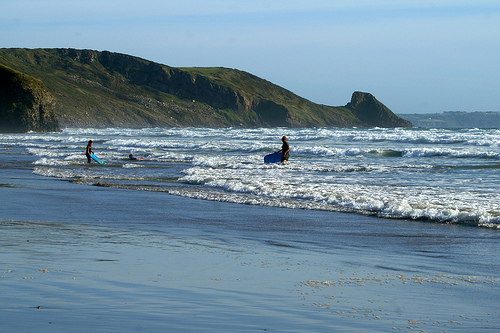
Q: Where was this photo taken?
A: On the ocean.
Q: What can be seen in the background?
A: A hill.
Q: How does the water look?
A: Rough.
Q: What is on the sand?
A: Water.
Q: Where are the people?
A: In the water.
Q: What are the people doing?
A: Surfing.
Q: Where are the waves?
A: Rolling to shore.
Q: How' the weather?
A: Partly cloudy.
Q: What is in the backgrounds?
A: Hills.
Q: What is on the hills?
A: Grass.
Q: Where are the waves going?
A: On the beach.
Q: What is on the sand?
A: Foam bubbles.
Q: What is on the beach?
A: Sand.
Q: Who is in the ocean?
A: Two surfers.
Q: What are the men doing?
A: Surfing.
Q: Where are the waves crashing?
A: On the shore.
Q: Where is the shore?
A: In the front ocean.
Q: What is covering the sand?
A: The ocean water.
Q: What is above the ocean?
A: Clear blue sky.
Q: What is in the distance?
A: A largecliff.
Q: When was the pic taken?
A: During the day.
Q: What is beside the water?
A: Hill.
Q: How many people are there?
A: 3.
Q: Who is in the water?
A: A child.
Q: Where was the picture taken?
A: In the oean.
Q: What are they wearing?
A: Swimsuit.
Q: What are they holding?
A: Surfboards.